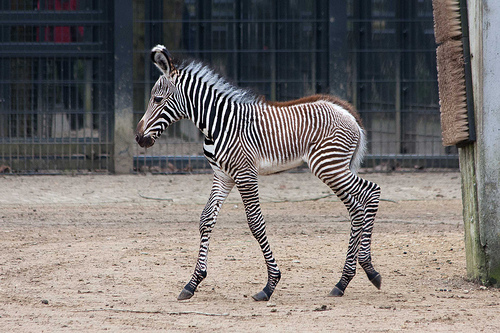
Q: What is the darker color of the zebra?
A: Black.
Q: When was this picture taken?
A: Daytime.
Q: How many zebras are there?
A: One.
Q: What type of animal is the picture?
A: Zebra.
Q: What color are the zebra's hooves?
A: Black.